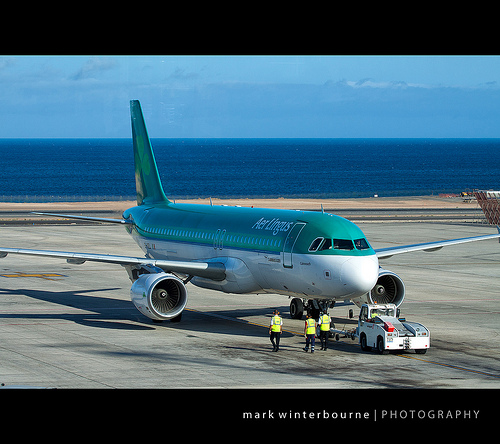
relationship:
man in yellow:
[265, 313, 285, 340] [272, 316, 284, 338]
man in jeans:
[265, 313, 285, 340] [267, 332, 284, 351]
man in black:
[265, 313, 285, 340] [267, 332, 284, 351]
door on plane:
[281, 221, 306, 269] [122, 100, 418, 316]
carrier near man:
[356, 302, 437, 357] [268, 309, 284, 353]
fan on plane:
[133, 269, 189, 326] [122, 100, 418, 316]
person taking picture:
[241, 406, 374, 427] [6, 5, 496, 433]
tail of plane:
[120, 93, 173, 205] [122, 100, 418, 316]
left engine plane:
[364, 268, 404, 310] [122, 100, 418, 316]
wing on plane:
[7, 240, 213, 274] [122, 100, 418, 316]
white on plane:
[254, 217, 294, 232] [122, 100, 418, 316]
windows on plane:
[126, 221, 285, 250] [122, 100, 418, 316]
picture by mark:
[233, 412, 478, 424] [244, 406, 279, 424]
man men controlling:
[268, 309, 284, 353] [266, 316, 334, 340]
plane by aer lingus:
[122, 100, 418, 316] [254, 217, 294, 232]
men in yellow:
[266, 316, 334, 340] [272, 316, 284, 338]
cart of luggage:
[356, 302, 437, 357] [360, 310, 418, 356]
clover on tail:
[131, 171, 149, 195] [120, 93, 173, 205]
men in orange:
[266, 316, 334, 340] [271, 315, 276, 317]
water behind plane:
[2, 132, 497, 190] [122, 100, 418, 316]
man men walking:
[268, 309, 284, 353] [269, 329, 336, 355]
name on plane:
[251, 215, 302, 235] [122, 100, 418, 316]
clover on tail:
[135, 171, 148, 195] [120, 93, 173, 205]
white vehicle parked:
[356, 302, 437, 357] [360, 310, 418, 356]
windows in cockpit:
[308, 234, 371, 252] [315, 231, 382, 265]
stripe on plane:
[139, 231, 288, 262] [122, 100, 418, 316]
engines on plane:
[128, 266, 404, 313] [122, 100, 418, 316]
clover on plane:
[131, 171, 149, 195] [122, 100, 418, 316]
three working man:
[266, 316, 334, 340] [268, 309, 284, 353]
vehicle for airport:
[356, 302, 437, 357] [122, 100, 418, 316]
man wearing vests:
[268, 309, 284, 353] [266, 316, 334, 340]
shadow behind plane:
[19, 280, 274, 348] [122, 100, 418, 316]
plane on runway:
[122, 100, 418, 316] [12, 212, 490, 393]